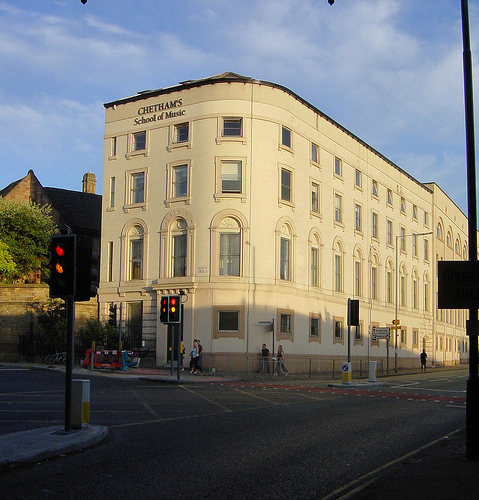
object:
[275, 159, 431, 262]
windows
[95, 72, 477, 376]
building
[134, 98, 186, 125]
words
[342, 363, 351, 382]
box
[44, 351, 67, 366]
bike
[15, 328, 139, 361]
fence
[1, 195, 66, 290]
tree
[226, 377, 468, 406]
red crosswalk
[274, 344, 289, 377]
woman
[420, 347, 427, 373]
guy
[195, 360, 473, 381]
sidewalk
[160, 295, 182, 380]
stop light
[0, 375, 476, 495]
road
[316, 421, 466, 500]
line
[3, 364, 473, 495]
street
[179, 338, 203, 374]
people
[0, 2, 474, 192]
sky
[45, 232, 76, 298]
stop light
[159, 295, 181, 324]
stop light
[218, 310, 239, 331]
window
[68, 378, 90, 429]
box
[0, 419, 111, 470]
median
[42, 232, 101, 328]
stop light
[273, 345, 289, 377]
girl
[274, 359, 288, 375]
pants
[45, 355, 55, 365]
person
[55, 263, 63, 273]
light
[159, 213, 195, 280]
window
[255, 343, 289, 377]
couple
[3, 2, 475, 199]
blue sky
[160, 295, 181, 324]
stoplight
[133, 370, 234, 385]
corner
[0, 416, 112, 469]
island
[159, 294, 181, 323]
light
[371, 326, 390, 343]
signs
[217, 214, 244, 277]
window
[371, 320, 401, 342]
sign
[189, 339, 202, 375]
lady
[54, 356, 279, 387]
sidewalk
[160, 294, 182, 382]
traffic lights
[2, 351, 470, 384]
sidewalk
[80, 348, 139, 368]
barrier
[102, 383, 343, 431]
lines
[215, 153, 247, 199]
window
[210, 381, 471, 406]
median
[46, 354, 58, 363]
tire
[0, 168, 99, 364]
building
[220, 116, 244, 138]
window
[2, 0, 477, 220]
clouds